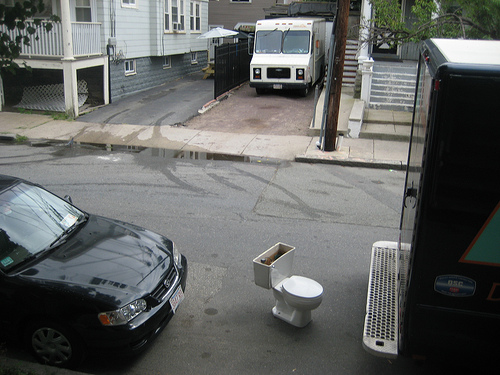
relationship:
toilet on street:
[247, 234, 322, 335] [57, 152, 366, 247]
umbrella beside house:
[195, 21, 238, 44] [89, 7, 206, 88]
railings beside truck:
[209, 37, 250, 99] [236, 11, 330, 103]